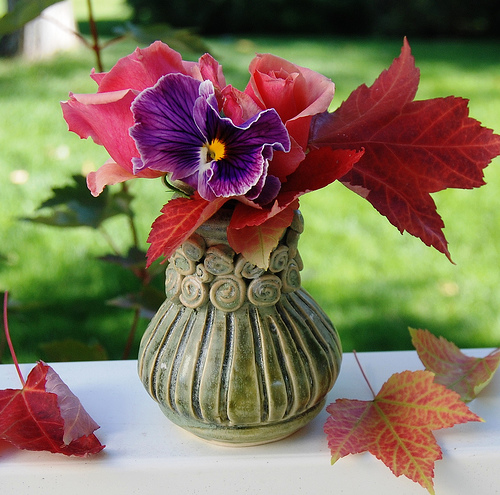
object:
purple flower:
[129, 71, 290, 210]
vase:
[131, 202, 352, 448]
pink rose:
[226, 52, 332, 121]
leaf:
[406, 324, 498, 414]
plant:
[1, 0, 223, 360]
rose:
[223, 52, 335, 176]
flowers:
[59, 35, 496, 271]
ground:
[428, 149, 458, 194]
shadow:
[360, 296, 467, 363]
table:
[4, 358, 490, 493]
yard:
[5, 61, 496, 353]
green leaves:
[41, 173, 105, 339]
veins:
[331, 365, 460, 483]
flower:
[160, 91, 252, 178]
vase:
[159, 281, 326, 406]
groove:
[247, 312, 312, 419]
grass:
[48, 262, 154, 376]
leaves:
[258, 60, 468, 221]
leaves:
[359, 297, 484, 459]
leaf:
[1, 336, 95, 468]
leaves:
[139, 183, 201, 268]